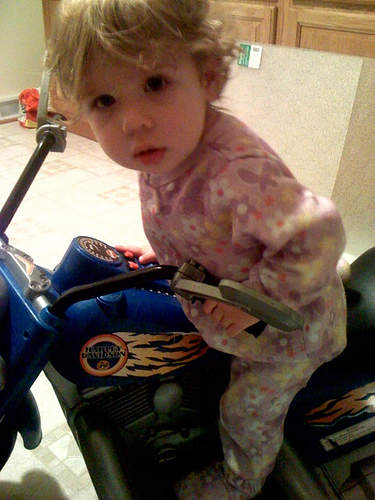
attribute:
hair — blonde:
[15, 9, 279, 96]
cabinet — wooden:
[42, 1, 372, 58]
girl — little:
[44, 0, 353, 495]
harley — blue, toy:
[13, 183, 372, 469]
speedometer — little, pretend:
[76, 232, 124, 272]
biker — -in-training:
[18, 21, 364, 434]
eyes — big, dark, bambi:
[84, 66, 170, 110]